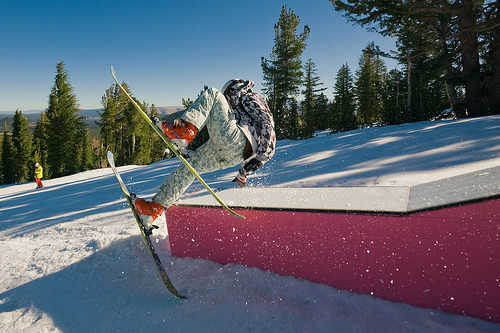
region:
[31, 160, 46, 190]
skier wearing a yellow jacket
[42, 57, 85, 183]
tall green pine tree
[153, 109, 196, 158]
red ski boot with white accent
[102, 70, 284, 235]
skier falling off a jump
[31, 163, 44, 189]
skier wearing red pants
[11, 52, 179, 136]
horizon framed by tall pine trees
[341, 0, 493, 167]
pine trees with shadows on the snow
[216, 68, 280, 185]
skier wearing a houndstooth check jacket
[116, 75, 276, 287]
skier trying to land a jump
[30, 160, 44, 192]
skier wearing red and yellow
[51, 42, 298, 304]
a person performing a stunt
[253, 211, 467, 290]
the red base on a platform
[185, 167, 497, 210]
the white top on a platform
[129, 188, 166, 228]
a red and white snow boot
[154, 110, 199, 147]
a red and white snow boot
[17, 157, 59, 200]
a person wearing a yellow jacket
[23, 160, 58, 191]
a person wearing red pants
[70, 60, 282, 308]
a man wearing a black and white jacket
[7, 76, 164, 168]
tall evergreen trees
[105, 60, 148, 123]
the end of a yellow ski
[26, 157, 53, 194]
man in yellow jacket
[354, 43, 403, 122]
pine tree in snow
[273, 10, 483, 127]
pine trees in snow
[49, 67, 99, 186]
tall pine tree in snow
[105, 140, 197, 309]
right ski in snow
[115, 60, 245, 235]
left ski on skier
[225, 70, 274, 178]
jacket on the man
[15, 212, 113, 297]
foot prints on the snow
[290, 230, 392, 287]
snow flying off the guy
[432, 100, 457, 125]
table in the snow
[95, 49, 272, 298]
skier in the snow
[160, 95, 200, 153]
boot on the skier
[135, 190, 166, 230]
boot on the skier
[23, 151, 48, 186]
skier in the snow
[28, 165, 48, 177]
yellow jacket on the skier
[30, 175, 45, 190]
red pants on the skier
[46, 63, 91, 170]
pine tree on the mountain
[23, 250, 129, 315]
shadow in the snow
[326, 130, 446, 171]
shadows in the snow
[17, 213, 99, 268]
snow on the mountain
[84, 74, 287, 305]
Skier wiping out on the snow.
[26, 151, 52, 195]
Skier dressed in yellow and red.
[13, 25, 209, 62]
Bright blue sky in the distance.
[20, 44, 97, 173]
Giant pine tree in the background.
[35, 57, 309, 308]
Skier losing his balance.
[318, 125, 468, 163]
A hill full of snow.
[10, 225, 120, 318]
Tracks in the snow.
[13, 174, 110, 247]
Shadows made by the shining sun.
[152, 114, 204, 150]
Bright red ski boots.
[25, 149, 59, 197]
One lonely skier on the slope.